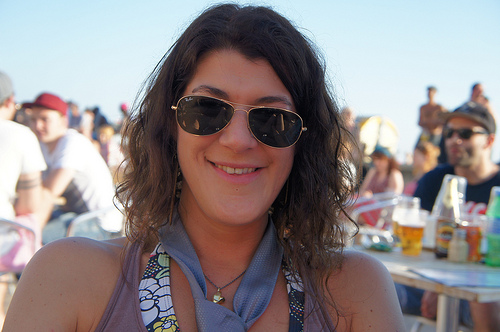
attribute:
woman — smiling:
[41, 4, 381, 329]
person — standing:
[422, 88, 442, 140]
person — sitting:
[363, 141, 399, 241]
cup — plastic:
[399, 214, 419, 252]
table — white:
[408, 258, 492, 298]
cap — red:
[32, 96, 64, 109]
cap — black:
[460, 100, 486, 122]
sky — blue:
[3, 4, 141, 64]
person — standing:
[471, 80, 484, 99]